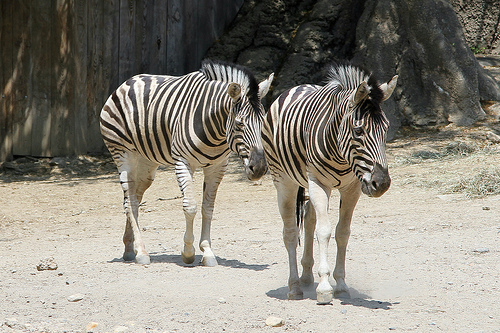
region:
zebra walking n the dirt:
[255, 60, 400, 309]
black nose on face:
[364, 163, 393, 202]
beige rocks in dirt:
[211, 297, 286, 328]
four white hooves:
[285, 265, 354, 305]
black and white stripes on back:
[115, 75, 207, 157]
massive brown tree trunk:
[206, 0, 497, 145]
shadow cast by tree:
[3, 8, 190, 166]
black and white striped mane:
[326, 59, 382, 107]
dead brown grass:
[439, 156, 499, 200]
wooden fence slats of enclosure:
[2, 8, 188, 157]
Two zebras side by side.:
[93, 55, 403, 306]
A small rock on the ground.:
[263, 311, 287, 331]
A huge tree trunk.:
[208, 0, 498, 143]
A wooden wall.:
[0, 2, 223, 156]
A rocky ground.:
[0, 154, 497, 331]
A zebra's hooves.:
[118, 240, 226, 269]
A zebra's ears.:
[225, 72, 275, 102]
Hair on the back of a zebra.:
[200, 60, 261, 114]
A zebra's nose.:
[368, 160, 390, 199]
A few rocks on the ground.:
[65, 285, 285, 327]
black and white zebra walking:
[82, 58, 277, 332]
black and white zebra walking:
[283, 57, 398, 329]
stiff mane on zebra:
[189, 52, 281, 100]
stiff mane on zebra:
[314, 50, 411, 112]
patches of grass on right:
[444, 173, 495, 226]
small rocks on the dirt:
[254, 309, 279, 331]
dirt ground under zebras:
[1, 160, 499, 327]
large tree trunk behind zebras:
[35, 10, 497, 183]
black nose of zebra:
[361, 163, 397, 198]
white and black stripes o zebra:
[125, 70, 200, 149]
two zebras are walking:
[131, 72, 401, 304]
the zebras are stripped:
[68, 52, 373, 263]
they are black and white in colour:
[52, 60, 392, 287]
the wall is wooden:
[4, 2, 99, 119]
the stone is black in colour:
[404, 3, 459, 88]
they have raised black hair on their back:
[142, 52, 409, 108]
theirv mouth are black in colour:
[228, 148, 287, 190]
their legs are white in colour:
[266, 182, 353, 306]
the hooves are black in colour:
[175, 248, 225, 265]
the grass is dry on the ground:
[414, 135, 499, 183]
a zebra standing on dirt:
[265, 67, 400, 304]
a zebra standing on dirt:
[97, 56, 269, 270]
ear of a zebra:
[227, 81, 242, 103]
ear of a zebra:
[351, 81, 367, 106]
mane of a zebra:
[199, 57, 259, 113]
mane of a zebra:
[324, 63, 383, 123]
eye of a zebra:
[233, 120, 244, 126]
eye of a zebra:
[351, 126, 363, 136]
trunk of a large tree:
[198, 3, 498, 140]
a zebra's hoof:
[316, 287, 332, 304]